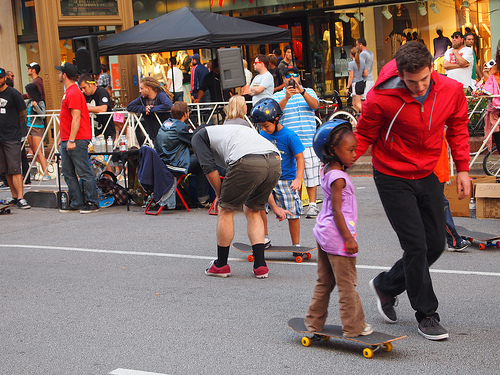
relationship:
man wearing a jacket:
[342, 44, 471, 341] [350, 58, 476, 176]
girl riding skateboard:
[308, 124, 377, 336] [286, 317, 405, 357]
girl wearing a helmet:
[308, 124, 377, 336] [310, 117, 352, 163]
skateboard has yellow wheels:
[286, 317, 405, 357] [300, 339, 399, 358]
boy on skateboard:
[252, 99, 312, 251] [232, 240, 315, 266]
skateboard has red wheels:
[232, 240, 315, 266] [247, 253, 309, 264]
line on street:
[5, 236, 499, 287] [5, 178, 499, 372]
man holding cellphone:
[267, 65, 323, 216] [285, 78, 298, 91]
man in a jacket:
[342, 44, 471, 341] [350, 58, 476, 176]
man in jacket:
[342, 44, 471, 341] [350, 58, 476, 176]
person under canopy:
[188, 55, 238, 105] [98, 7, 291, 58]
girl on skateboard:
[308, 124, 377, 336] [286, 317, 405, 357]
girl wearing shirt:
[308, 124, 377, 336] [314, 168, 363, 256]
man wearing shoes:
[191, 120, 278, 278] [207, 258, 272, 281]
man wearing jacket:
[342, 44, 471, 341] [350, 58, 476, 176]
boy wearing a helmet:
[252, 99, 312, 251] [251, 96, 282, 130]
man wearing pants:
[342, 44, 471, 341] [369, 169, 447, 313]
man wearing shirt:
[55, 83, 101, 203] [55, 87, 94, 143]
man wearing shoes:
[342, 44, 471, 341] [366, 273, 449, 343]